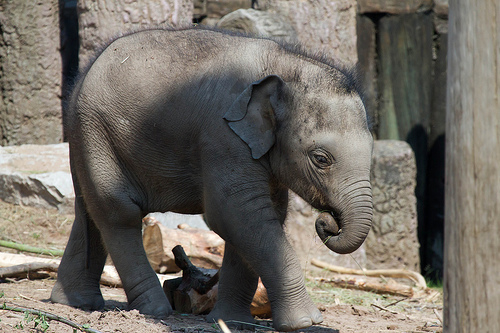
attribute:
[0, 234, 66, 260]
branch — green, tree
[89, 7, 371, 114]
hair — black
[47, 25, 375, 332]
elephant — a baby, small, baby, grey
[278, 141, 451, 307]
block — stone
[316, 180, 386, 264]
trunk — rolled-up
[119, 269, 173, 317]
foot — back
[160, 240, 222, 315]
branches — cut up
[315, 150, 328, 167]
eye — tired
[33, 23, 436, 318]
elephant — a baby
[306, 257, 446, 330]
sticks — small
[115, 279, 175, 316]
foot — back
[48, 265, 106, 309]
foot — back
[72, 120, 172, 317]
leg — back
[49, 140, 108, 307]
leg — back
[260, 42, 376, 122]
fur — small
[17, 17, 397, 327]
elephant — baby, a baby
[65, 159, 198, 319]
leg — back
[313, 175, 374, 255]
trunk — curled